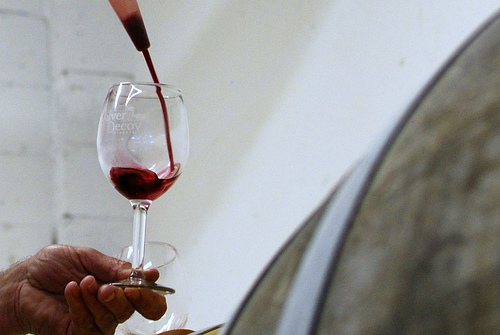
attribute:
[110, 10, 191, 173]
wine — red, clear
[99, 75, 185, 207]
glass — held, white, big, empty, red, clear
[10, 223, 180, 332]
hand — wrinkled, white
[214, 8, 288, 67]
wall — white, far